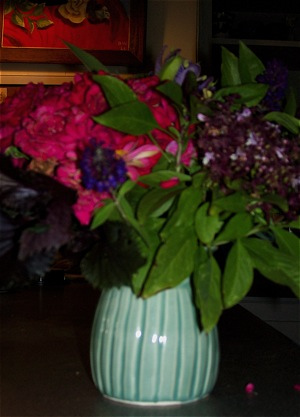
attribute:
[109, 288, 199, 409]
vase — ceramic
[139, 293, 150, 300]
tip — pointy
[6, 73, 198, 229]
flowers — pink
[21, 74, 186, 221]
flowers — red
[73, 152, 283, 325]
leaves — green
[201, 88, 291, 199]
flower — purple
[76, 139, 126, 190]
violet flower — blue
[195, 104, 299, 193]
violet flower — blue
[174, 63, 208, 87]
violet flower — blue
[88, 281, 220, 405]
bands — green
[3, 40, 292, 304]
flowers — bright, jade, arranged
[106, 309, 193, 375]
highlights — white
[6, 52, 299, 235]
flowers — purple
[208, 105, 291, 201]
flowers — purple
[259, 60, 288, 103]
flowers — purple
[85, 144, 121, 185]
flowers — purple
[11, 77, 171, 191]
flowers — purple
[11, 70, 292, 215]
flowers — purple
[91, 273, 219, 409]
vase — green, striped, glazed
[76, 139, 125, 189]
flower — purple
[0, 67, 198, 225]
pink flowers — bright pink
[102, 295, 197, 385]
vase — shiny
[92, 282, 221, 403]
flower vase — pale blue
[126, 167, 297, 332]
leaves — big, green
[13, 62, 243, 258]
flowers — pink 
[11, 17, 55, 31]
painting leaves — yellowish-green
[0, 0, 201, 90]
picture — red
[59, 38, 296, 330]
leaves — green 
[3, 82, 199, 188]
flower — pink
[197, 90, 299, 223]
flowers — purple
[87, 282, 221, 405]
vase — striped, ceramic, green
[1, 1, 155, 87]
picture — framed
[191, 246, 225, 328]
leaf — green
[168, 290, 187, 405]
line — thin